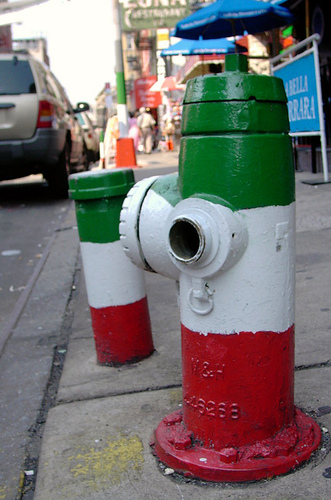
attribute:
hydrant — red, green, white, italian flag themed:
[126, 41, 330, 468]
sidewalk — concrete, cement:
[63, 127, 326, 499]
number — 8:
[230, 402, 239, 422]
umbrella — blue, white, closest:
[176, 3, 285, 36]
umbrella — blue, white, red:
[162, 34, 244, 60]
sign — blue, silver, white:
[270, 36, 322, 144]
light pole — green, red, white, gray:
[110, 7, 131, 156]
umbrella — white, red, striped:
[146, 74, 189, 96]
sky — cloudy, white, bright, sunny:
[12, 4, 129, 130]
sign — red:
[133, 77, 158, 110]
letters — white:
[135, 80, 160, 105]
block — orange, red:
[110, 139, 141, 168]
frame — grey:
[257, 37, 327, 177]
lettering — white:
[284, 74, 311, 119]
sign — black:
[114, 1, 240, 30]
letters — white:
[123, 2, 202, 29]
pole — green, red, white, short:
[65, 165, 152, 369]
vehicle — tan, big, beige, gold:
[0, 49, 88, 191]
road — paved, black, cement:
[6, 170, 71, 498]